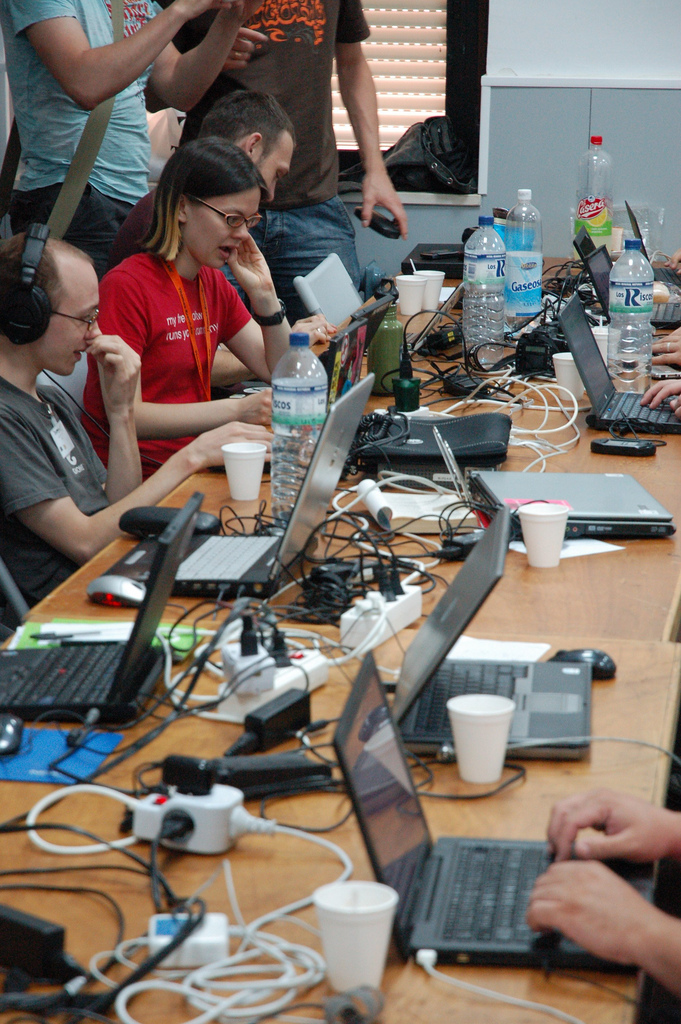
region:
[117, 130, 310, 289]
a view of face of the person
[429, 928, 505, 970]
a view of ports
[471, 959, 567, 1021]
a view of wires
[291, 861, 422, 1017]
a view of cup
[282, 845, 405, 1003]
a cup in table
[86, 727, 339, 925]
a view of plugs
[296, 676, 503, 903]
a view of laptop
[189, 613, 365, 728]
a view of plug box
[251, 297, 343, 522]
a view of bottle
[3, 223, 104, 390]
the head of a man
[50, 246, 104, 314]
the forehead of a man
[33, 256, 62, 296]
the hair of a man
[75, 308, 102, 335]
the eyes of a man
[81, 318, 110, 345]
the nose of a man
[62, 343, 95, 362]
the mouth of a man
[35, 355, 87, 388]
the chin of a man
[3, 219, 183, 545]
a man picking his nose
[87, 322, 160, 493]
the left arm of a man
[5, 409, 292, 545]
the right arm of a man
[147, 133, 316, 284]
the head of a woman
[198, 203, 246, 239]
the eye of a woman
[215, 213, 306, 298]
the hand of a woman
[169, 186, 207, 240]
the ear of a woman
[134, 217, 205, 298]
the neck of a woman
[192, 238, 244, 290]
the chin of a woman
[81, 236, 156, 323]
the shoulder of a woman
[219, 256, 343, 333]
the wrist of a woman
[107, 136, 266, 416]
a person in a red shirt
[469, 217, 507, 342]
a water bottle on the table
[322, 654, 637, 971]
a laptop on the table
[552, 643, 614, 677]
a black computer mouse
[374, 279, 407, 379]
a green bottle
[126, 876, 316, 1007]
cords on the desk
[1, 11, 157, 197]
a person in a blue shirt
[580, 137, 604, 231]
a bottle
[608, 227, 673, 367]
water on a table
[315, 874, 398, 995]
cup on a table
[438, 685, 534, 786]
cup on a table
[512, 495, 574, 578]
cup on a table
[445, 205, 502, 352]
water on a table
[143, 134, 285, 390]
woman wearing red shirt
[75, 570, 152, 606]
mouse on a table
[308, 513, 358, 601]
cords on a table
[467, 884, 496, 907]
a button on the keyboard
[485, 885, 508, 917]
a button on the keyboard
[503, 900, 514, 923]
a button on the keyboard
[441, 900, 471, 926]
a button on the keyboard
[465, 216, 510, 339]
a tall plastic water bottle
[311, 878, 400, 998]
a small white styrofoam cup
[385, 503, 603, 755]
a black laptop computer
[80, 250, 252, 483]
a woman's short sleeve red and white shirt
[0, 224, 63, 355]
large black headphones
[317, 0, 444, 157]
white window blinds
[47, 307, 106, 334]
the side of a man's eyeglasses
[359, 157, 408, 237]
the hand of a man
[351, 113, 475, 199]
a large black bag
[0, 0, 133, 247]
a long green strap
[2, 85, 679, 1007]
group of young people working on computers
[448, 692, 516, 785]
white styrofoam sitting on the table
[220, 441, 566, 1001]
four styrofoam cups sitting on the table